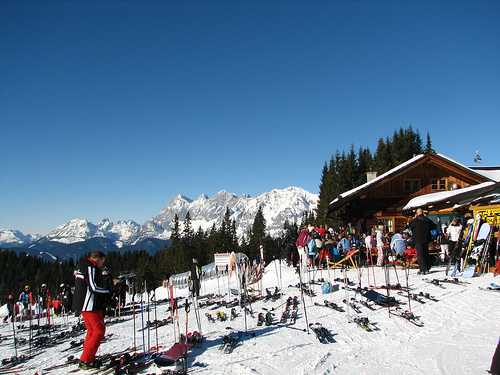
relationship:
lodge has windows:
[323, 151, 497, 267] [399, 176, 452, 194]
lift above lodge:
[467, 142, 488, 172] [323, 151, 497, 267]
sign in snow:
[206, 243, 232, 272] [34, 281, 482, 371]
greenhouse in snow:
[158, 248, 264, 284] [34, 281, 482, 371]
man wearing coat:
[65, 247, 120, 373] [57, 258, 119, 313]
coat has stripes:
[57, 258, 119, 313] [81, 264, 98, 314]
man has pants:
[65, 247, 120, 373] [70, 308, 111, 374]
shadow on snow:
[200, 315, 293, 352] [34, 281, 482, 371]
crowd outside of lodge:
[271, 209, 416, 276] [323, 151, 497, 267]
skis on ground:
[308, 319, 336, 351] [34, 281, 482, 371]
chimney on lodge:
[365, 164, 376, 182] [323, 151, 497, 267]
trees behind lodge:
[314, 120, 445, 190] [323, 151, 497, 267]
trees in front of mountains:
[69, 209, 301, 273] [41, 185, 331, 233]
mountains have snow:
[41, 185, 331, 233] [257, 178, 303, 217]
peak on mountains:
[172, 189, 188, 206] [41, 185, 331, 233]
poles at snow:
[124, 276, 211, 372] [34, 281, 482, 371]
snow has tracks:
[34, 281, 482, 371] [252, 310, 480, 370]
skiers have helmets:
[9, 280, 78, 321] [9, 280, 74, 294]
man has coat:
[412, 205, 443, 282] [403, 214, 441, 247]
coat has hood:
[403, 214, 441, 247] [414, 215, 432, 225]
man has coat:
[443, 216, 467, 282] [444, 222, 471, 243]